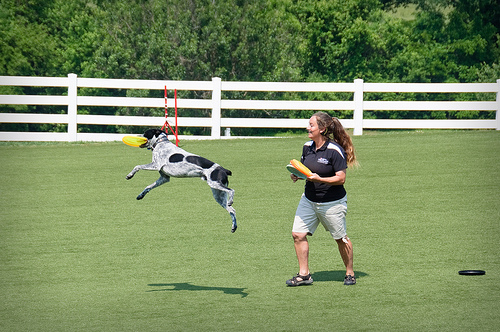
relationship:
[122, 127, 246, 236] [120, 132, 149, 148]
dog has frisbee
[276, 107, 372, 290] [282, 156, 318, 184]
woman holding discs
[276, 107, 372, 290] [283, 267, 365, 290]
woman has feet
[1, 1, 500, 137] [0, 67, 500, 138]
trees behind fence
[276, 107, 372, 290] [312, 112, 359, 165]
woman has ponytail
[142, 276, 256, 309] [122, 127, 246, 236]
shadow under dog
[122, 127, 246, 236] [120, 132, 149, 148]
dog with frisbee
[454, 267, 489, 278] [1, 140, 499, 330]
disc in grass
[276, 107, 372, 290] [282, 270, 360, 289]
woman in sandals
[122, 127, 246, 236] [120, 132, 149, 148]
dog has a frisbee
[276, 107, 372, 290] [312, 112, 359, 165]
woman wearing ponytail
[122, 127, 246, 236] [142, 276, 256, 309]
dog has shadow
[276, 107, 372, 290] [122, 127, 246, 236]
woman with dog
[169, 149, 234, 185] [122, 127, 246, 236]
spots on dog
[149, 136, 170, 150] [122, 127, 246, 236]
collar on dog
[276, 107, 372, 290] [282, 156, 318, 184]
woman carrying discs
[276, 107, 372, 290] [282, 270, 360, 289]
woman wearing sandals